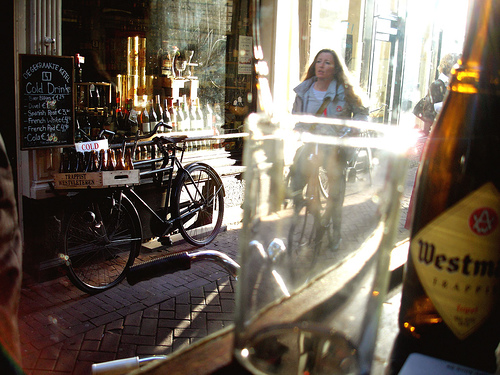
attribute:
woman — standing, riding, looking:
[294, 49, 369, 121]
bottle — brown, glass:
[398, 1, 498, 361]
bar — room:
[0, 1, 499, 373]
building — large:
[1, 0, 496, 272]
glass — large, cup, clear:
[232, 111, 414, 373]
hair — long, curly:
[302, 47, 364, 109]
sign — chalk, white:
[20, 51, 77, 153]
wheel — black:
[178, 167, 227, 246]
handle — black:
[97, 127, 120, 138]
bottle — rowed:
[58, 148, 135, 175]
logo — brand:
[53, 172, 100, 186]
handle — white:
[159, 121, 174, 134]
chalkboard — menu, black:
[17, 50, 81, 149]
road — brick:
[3, 163, 417, 372]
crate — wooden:
[54, 165, 141, 191]